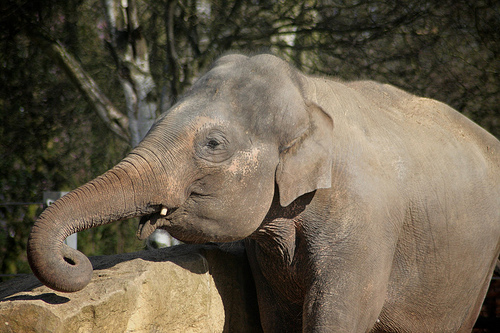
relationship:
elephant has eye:
[23, 52, 499, 332] [205, 138, 221, 148]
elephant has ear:
[23, 52, 499, 332] [272, 102, 335, 210]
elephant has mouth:
[23, 52, 499, 332] [134, 204, 173, 243]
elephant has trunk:
[23, 52, 499, 332] [23, 143, 169, 294]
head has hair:
[131, 50, 317, 250] [199, 45, 296, 61]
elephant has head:
[23, 52, 499, 332] [131, 50, 317, 250]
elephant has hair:
[23, 52, 499, 332] [199, 45, 296, 61]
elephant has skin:
[23, 52, 499, 332] [25, 50, 498, 330]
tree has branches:
[0, 10, 500, 282] [170, 0, 498, 135]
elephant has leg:
[23, 52, 499, 332] [300, 283, 387, 332]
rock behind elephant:
[4, 239, 232, 331] [23, 52, 499, 332]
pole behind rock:
[40, 188, 79, 256] [4, 239, 232, 331]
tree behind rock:
[0, 10, 500, 282] [4, 239, 232, 331]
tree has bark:
[0, 10, 500, 282] [49, 0, 323, 248]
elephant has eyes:
[23, 52, 499, 332] [206, 136, 220, 149]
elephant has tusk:
[23, 52, 499, 332] [159, 204, 169, 217]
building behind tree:
[0, 0, 497, 275] [0, 10, 500, 282]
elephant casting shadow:
[23, 52, 499, 332] [1, 243, 264, 332]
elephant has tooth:
[23, 52, 499, 332] [160, 205, 168, 218]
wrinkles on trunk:
[99, 139, 174, 206] [24, 127, 186, 293]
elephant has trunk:
[23, 52, 499, 332] [24, 127, 186, 293]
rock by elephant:
[4, 239, 232, 331] [23, 52, 499, 332]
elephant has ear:
[23, 52, 499, 332] [257, 104, 344, 208]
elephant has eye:
[23, 52, 499, 332] [175, 119, 252, 169]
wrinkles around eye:
[187, 119, 247, 171] [175, 119, 252, 169]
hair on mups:
[204, 50, 287, 77] [212, 44, 294, 81]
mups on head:
[212, 44, 294, 81] [20, 42, 335, 292]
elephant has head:
[23, 52, 499, 332] [20, 42, 335, 292]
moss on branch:
[64, 24, 126, 160] [48, 38, 138, 138]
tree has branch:
[0, 10, 500, 282] [48, 38, 138, 138]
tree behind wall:
[0, 10, 500, 282] [7, 247, 237, 331]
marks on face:
[224, 141, 267, 181] [143, 76, 281, 210]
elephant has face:
[23, 52, 499, 332] [143, 76, 281, 210]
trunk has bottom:
[12, 137, 195, 291] [39, 234, 94, 286]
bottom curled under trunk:
[39, 234, 94, 286] [12, 137, 195, 291]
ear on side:
[274, 108, 336, 205] [201, 73, 322, 223]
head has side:
[25, 50, 315, 313] [201, 73, 322, 223]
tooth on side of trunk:
[160, 205, 168, 218] [23, 143, 169, 294]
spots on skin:
[133, 148, 195, 210] [75, 111, 297, 233]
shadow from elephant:
[159, 225, 322, 329] [23, 52, 499, 332]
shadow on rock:
[0, 289, 75, 307] [7, 251, 243, 331]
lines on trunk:
[94, 136, 176, 202] [32, 132, 201, 292]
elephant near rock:
[23, 52, 499, 332] [4, 239, 232, 331]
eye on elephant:
[193, 122, 240, 166] [31, 38, 472, 331]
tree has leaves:
[278, 10, 484, 110] [408, 25, 460, 63]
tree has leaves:
[0, 10, 500, 282] [33, 93, 80, 142]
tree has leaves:
[0, 10, 500, 282] [24, 26, 63, 65]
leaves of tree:
[377, 43, 404, 73] [13, 10, 484, 303]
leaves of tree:
[314, 24, 354, 59] [13, 10, 483, 266]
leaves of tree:
[361, 14, 386, 44] [13, 10, 484, 303]